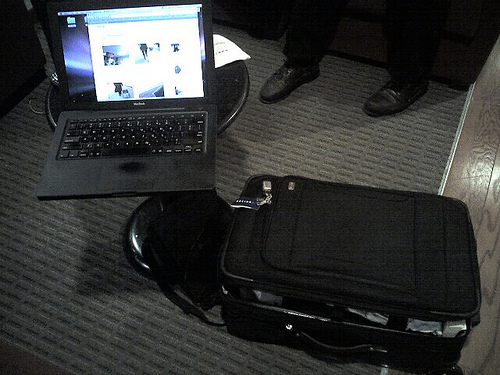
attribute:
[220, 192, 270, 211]
tag — silver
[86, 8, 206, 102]
page — open 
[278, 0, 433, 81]
pants — black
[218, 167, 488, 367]
suitcase — open, black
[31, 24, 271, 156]
table — black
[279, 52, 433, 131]
shoes — Black 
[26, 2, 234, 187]
computer — on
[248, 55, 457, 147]
shoes — black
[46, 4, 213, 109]
screen — on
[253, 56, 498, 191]
shoes — Black 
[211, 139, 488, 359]
suitcase — open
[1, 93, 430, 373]
gray carpet — Black 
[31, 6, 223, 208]
lap top — on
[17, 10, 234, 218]
computer — black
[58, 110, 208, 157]
keyboard — black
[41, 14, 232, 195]
laptop — black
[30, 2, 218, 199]
laptop — black, on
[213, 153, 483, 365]
suitcase — Black 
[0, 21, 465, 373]
carpet — grey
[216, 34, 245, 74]
paper — white 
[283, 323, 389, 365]
handle — Black 